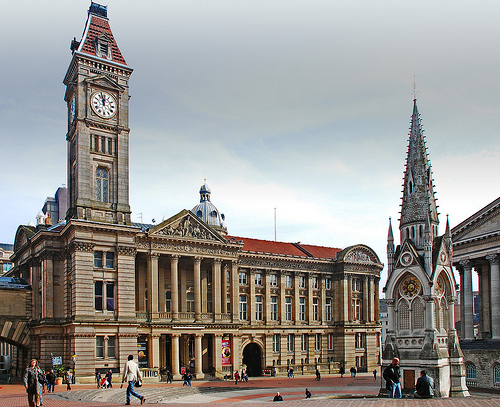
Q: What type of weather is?
A: It is overcast.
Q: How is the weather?
A: It is overcast.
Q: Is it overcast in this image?
A: Yes, it is overcast.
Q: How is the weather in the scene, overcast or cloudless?
A: It is overcast.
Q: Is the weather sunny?
A: No, it is overcast.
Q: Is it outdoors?
A: Yes, it is outdoors.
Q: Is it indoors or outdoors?
A: It is outdoors.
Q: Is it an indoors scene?
A: No, it is outdoors.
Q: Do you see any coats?
A: Yes, there is a coat.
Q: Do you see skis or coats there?
A: Yes, there is a coat.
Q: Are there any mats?
A: No, there are no mats.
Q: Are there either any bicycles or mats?
A: No, there are no mats or bicycles.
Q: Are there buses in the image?
A: No, there are no buses.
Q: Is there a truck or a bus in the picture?
A: No, there are no buses or trucks.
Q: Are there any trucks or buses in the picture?
A: No, there are no buses or trucks.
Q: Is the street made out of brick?
A: Yes, the street is made of brick.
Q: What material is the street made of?
A: The street is made of brick.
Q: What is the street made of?
A: The street is made of brick.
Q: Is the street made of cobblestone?
A: No, the street is made of brick.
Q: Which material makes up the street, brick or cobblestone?
A: The street is made of brick.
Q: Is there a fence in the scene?
A: No, there are no fences.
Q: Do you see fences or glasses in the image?
A: No, there are no fences or glasses.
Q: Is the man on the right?
A: Yes, the man is on the right of the image.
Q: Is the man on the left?
A: No, the man is on the right of the image.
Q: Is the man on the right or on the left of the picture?
A: The man is on the right of the image.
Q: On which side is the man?
A: The man is on the right of the image.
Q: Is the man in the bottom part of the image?
A: Yes, the man is in the bottom of the image.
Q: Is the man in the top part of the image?
A: No, the man is in the bottom of the image.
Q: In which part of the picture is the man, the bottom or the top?
A: The man is in the bottom of the image.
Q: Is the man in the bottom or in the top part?
A: The man is in the bottom of the image.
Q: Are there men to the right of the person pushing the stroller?
A: Yes, there is a man to the right of the person.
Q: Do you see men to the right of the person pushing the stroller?
A: Yes, there is a man to the right of the person.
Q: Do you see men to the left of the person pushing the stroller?
A: No, the man is to the right of the person.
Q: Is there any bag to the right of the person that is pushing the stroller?
A: No, there is a man to the right of the person.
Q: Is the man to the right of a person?
A: Yes, the man is to the right of a person.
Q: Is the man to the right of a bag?
A: No, the man is to the right of a person.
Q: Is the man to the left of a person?
A: No, the man is to the right of a person.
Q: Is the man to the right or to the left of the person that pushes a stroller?
A: The man is to the right of the person.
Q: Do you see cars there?
A: No, there are no cars.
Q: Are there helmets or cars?
A: No, there are no cars or helmets.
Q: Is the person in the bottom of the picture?
A: Yes, the person is in the bottom of the image.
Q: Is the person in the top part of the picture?
A: No, the person is in the bottom of the image.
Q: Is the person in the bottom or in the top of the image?
A: The person is in the bottom of the image.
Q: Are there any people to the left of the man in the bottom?
A: Yes, there is a person to the left of the man.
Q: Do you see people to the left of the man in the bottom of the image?
A: Yes, there is a person to the left of the man.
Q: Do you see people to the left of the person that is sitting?
A: Yes, there is a person to the left of the man.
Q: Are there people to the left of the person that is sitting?
A: Yes, there is a person to the left of the man.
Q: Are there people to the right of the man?
A: No, the person is to the left of the man.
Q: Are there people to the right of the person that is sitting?
A: No, the person is to the left of the man.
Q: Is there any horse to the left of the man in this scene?
A: No, there is a person to the left of the man.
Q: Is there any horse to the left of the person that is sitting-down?
A: No, there is a person to the left of the man.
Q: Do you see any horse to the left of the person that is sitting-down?
A: No, there is a person to the left of the man.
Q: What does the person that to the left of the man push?
A: The person pushes a stroller.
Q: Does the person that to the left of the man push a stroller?
A: Yes, the person pushes a stroller.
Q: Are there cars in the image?
A: No, there are no cars.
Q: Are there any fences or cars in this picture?
A: No, there are no cars or fences.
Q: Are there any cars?
A: No, there are no cars.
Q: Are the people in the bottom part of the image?
A: Yes, the people are in the bottom of the image.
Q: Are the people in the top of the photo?
A: No, the people are in the bottom of the image.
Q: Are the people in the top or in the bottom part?
A: The people are in the bottom of the image.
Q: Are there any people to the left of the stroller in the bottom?
A: Yes, there are people to the left of the stroller.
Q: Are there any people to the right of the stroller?
A: No, the people are to the left of the stroller.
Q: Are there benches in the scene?
A: No, there are no benches.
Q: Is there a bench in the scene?
A: No, there are no benches.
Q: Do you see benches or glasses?
A: No, there are no benches or glasses.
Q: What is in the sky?
A: The clouds are in the sky.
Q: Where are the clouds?
A: The clouds are in the sky.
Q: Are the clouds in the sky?
A: Yes, the clouds are in the sky.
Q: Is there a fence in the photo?
A: No, there are no fences.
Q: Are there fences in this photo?
A: No, there are no fences.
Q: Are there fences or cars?
A: No, there are no fences or cars.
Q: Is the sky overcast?
A: Yes, the sky is overcast.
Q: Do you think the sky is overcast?
A: Yes, the sky is overcast.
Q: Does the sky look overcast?
A: Yes, the sky is overcast.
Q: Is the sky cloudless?
A: No, the sky is overcast.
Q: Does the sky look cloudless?
A: No, the sky is overcast.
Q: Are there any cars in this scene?
A: No, there are no cars.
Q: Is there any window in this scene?
A: Yes, there are windows.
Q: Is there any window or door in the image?
A: Yes, there are windows.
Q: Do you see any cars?
A: No, there are no cars.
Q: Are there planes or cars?
A: No, there are no cars or planes.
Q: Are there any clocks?
A: Yes, there is a clock.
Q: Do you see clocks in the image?
A: Yes, there is a clock.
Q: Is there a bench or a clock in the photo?
A: Yes, there is a clock.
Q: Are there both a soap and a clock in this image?
A: No, there is a clock but no soaps.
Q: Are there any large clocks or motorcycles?
A: Yes, there is a large clock.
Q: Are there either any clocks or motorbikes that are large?
A: Yes, the clock is large.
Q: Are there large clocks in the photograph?
A: Yes, there is a large clock.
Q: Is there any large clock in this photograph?
A: Yes, there is a large clock.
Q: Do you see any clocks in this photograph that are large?
A: Yes, there is a clock that is large.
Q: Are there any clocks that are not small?
A: Yes, there is a large clock.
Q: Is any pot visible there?
A: No, there are no pots.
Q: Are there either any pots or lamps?
A: No, there are no pots or lamps.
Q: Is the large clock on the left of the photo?
A: Yes, the clock is on the left of the image.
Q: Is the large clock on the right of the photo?
A: No, the clock is on the left of the image.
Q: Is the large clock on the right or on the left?
A: The clock is on the left of the image.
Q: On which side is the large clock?
A: The clock is on the left of the image.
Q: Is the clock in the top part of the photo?
A: Yes, the clock is in the top of the image.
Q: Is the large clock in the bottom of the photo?
A: No, the clock is in the top of the image.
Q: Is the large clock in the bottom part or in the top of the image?
A: The clock is in the top of the image.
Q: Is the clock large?
A: Yes, the clock is large.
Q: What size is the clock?
A: The clock is large.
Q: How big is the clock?
A: The clock is large.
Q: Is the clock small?
A: No, the clock is large.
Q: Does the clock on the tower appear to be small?
A: No, the clock is large.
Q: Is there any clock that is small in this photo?
A: No, there is a clock but it is large.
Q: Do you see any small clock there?
A: No, there is a clock but it is large.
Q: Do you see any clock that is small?
A: No, there is a clock but it is large.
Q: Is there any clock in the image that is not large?
A: No, there is a clock but it is large.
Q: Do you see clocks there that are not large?
A: No, there is a clock but it is large.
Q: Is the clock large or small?
A: The clock is large.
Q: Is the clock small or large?
A: The clock is large.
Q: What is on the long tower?
A: The clock is on the tower.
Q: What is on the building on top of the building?
A: The clock is on the tower.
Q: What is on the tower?
A: The clock is on the tower.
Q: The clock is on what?
A: The clock is on the tower.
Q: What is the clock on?
A: The clock is on the tower.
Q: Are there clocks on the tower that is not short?
A: Yes, there is a clock on the tower.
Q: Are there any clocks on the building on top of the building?
A: Yes, there is a clock on the tower.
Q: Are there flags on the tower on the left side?
A: No, there is a clock on the tower.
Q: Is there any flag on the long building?
A: No, there is a clock on the tower.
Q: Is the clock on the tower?
A: Yes, the clock is on the tower.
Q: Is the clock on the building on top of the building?
A: Yes, the clock is on the tower.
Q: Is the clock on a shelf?
A: No, the clock is on the tower.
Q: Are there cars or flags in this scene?
A: No, there are no cars or flags.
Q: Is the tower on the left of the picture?
A: Yes, the tower is on the left of the image.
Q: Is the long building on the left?
A: Yes, the tower is on the left of the image.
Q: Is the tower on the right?
A: No, the tower is on the left of the image.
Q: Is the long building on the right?
A: No, the tower is on the left of the image.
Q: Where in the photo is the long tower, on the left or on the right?
A: The tower is on the left of the image.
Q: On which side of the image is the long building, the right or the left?
A: The tower is on the left of the image.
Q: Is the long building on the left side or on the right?
A: The tower is on the left of the image.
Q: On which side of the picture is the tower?
A: The tower is on the left of the image.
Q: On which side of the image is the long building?
A: The tower is on the left of the image.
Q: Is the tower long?
A: Yes, the tower is long.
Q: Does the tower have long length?
A: Yes, the tower is long.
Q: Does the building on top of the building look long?
A: Yes, the tower is long.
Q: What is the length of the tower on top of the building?
A: The tower is long.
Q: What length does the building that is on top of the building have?
A: The tower has long length.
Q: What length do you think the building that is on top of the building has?
A: The tower has long length.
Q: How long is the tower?
A: The tower is long.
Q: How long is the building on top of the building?
A: The tower is long.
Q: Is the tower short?
A: No, the tower is long.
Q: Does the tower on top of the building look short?
A: No, the tower is long.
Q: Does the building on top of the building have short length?
A: No, the tower is long.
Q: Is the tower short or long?
A: The tower is long.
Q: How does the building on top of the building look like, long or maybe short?
A: The tower is long.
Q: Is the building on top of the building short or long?
A: The tower is long.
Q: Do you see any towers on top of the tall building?
A: Yes, there is a tower on top of the building.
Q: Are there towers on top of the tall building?
A: Yes, there is a tower on top of the building.